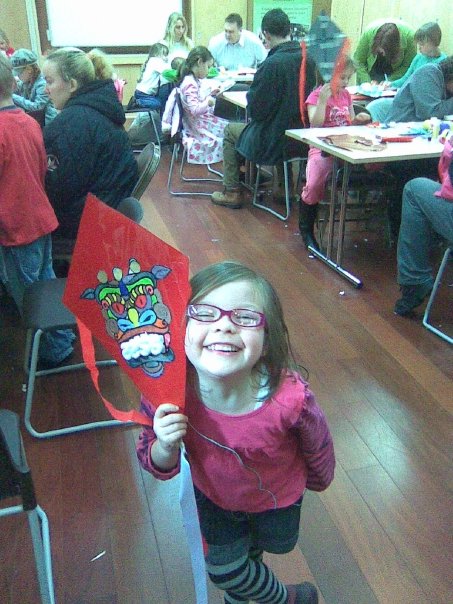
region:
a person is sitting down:
[24, 42, 130, 227]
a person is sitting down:
[389, 141, 445, 328]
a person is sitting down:
[295, 53, 373, 252]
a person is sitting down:
[379, 56, 452, 127]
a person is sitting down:
[211, 5, 317, 213]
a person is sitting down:
[165, 45, 236, 160]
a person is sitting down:
[127, 46, 176, 110]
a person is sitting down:
[208, 13, 268, 79]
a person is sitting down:
[154, 11, 191, 56]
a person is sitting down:
[5, 47, 48, 121]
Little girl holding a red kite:
[58, 188, 339, 602]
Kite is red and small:
[59, 187, 194, 447]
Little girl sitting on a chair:
[159, 46, 245, 203]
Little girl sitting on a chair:
[295, 52, 409, 257]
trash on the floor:
[87, 547, 110, 564]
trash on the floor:
[338, 286, 347, 294]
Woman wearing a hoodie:
[35, 43, 143, 279]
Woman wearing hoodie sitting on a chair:
[34, 44, 163, 275]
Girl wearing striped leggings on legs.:
[204, 543, 286, 603]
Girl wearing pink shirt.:
[115, 384, 331, 509]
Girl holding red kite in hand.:
[41, 222, 200, 440]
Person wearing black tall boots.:
[290, 189, 323, 256]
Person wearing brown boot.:
[208, 181, 246, 210]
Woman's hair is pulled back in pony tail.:
[41, 47, 123, 79]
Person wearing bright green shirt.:
[353, 23, 412, 85]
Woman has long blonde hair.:
[164, 9, 195, 58]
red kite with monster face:
[63, 190, 191, 418]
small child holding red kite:
[59, 189, 339, 568]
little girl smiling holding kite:
[61, 190, 339, 500]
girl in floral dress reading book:
[175, 45, 239, 163]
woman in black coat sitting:
[45, 48, 168, 236]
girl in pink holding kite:
[296, 10, 384, 257]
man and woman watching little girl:
[130, 11, 270, 106]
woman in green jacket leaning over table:
[352, 18, 421, 96]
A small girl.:
[146, 253, 356, 599]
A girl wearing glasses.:
[150, 248, 343, 598]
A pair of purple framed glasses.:
[179, 299, 263, 326]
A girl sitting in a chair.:
[161, 45, 241, 197]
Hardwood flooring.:
[8, 145, 446, 598]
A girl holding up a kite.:
[42, 201, 363, 585]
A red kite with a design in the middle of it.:
[58, 192, 189, 408]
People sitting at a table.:
[2, 18, 450, 291]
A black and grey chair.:
[18, 195, 187, 439]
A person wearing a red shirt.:
[0, 53, 65, 372]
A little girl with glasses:
[160, 292, 315, 575]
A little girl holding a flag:
[76, 277, 305, 564]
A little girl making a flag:
[299, 50, 433, 215]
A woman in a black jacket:
[41, 45, 136, 241]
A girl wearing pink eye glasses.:
[184, 299, 265, 333]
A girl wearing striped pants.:
[203, 557, 289, 602]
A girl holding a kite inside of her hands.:
[57, 190, 205, 470]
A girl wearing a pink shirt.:
[132, 384, 332, 516]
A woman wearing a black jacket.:
[47, 75, 138, 211]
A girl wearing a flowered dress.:
[178, 79, 230, 166]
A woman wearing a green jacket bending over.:
[347, 11, 416, 79]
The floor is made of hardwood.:
[347, 357, 449, 602]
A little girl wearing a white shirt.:
[138, 50, 171, 92]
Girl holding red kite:
[72, 267, 353, 593]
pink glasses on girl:
[174, 294, 273, 334]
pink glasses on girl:
[179, 299, 275, 329]